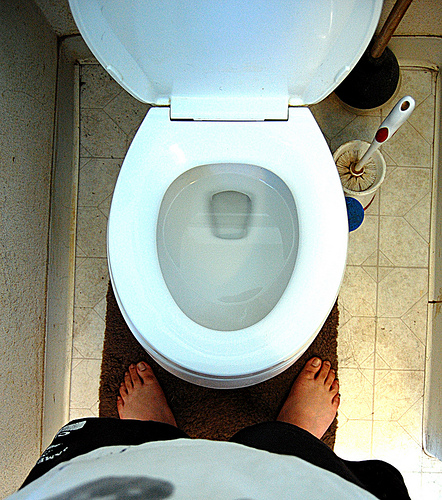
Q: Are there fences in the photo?
A: No, there are no fences.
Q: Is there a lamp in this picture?
A: No, there are no lamps.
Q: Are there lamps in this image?
A: No, there are no lamps.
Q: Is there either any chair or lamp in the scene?
A: No, there are no lamps or chairs.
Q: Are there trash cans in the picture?
A: No, there are no trash cans.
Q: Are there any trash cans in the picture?
A: No, there are no trash cans.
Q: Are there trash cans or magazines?
A: No, there are no trash cans or magazines.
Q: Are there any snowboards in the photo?
A: No, there are no snowboards.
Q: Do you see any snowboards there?
A: No, there are no snowboards.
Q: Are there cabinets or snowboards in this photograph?
A: No, there are no snowboards or cabinets.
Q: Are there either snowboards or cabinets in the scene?
A: No, there are no snowboards or cabinets.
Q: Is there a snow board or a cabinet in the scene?
A: No, there are no snowboards or cabinets.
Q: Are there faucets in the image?
A: No, there are no faucets.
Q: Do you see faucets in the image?
A: No, there are no faucets.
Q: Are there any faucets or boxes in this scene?
A: No, there are no faucets or boxes.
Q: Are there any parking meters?
A: No, there are no parking meters.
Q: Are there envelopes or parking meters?
A: No, there are no parking meters or envelopes.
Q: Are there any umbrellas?
A: No, there are no umbrellas.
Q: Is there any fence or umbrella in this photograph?
A: No, there are no umbrellas or fences.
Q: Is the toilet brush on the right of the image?
A: Yes, the toilet brush is on the right of the image.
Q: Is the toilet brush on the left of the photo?
A: No, the toilet brush is on the right of the image.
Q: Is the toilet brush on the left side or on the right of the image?
A: The toilet brush is on the right of the image.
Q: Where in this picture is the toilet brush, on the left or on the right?
A: The toilet brush is on the right of the image.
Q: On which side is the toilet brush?
A: The toilet brush is on the right of the image.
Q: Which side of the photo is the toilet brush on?
A: The toilet brush is on the right of the image.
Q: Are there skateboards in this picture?
A: No, there are no skateboards.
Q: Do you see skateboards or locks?
A: No, there are no skateboards or locks.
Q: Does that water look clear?
A: Yes, the water is clear.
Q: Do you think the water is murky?
A: No, the water is clear.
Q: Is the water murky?
A: No, the water is clear.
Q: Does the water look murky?
A: No, the water is clear.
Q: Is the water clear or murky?
A: The water is clear.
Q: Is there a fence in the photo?
A: No, there are no fences.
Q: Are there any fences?
A: No, there are no fences.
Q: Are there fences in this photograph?
A: No, there are no fences.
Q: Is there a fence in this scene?
A: No, there are no fences.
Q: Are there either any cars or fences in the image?
A: No, there are no fences or cars.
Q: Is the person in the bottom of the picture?
A: Yes, the person is in the bottom of the image.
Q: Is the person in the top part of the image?
A: No, the person is in the bottom of the image.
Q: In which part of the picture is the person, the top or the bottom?
A: The person is in the bottom of the image.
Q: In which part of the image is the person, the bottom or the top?
A: The person is in the bottom of the image.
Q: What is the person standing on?
A: The person is standing on the rug.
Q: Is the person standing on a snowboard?
A: No, the person is standing on the rug.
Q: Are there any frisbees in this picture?
A: No, there are no frisbees.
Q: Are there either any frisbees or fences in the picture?
A: No, there are no frisbees or fences.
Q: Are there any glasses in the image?
A: No, there are no glasses.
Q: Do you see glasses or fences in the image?
A: No, there are no glasses or fences.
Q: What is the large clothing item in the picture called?
A: The clothing item is a shirt.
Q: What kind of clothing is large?
A: The clothing is a shirt.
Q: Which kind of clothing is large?
A: The clothing is a shirt.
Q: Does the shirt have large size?
A: Yes, the shirt is large.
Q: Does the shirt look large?
A: Yes, the shirt is large.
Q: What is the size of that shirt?
A: The shirt is large.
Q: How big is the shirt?
A: The shirt is large.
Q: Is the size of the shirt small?
A: No, the shirt is large.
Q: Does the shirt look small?
A: No, the shirt is large.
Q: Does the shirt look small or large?
A: The shirt is large.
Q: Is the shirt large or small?
A: The shirt is large.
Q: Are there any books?
A: No, there are no books.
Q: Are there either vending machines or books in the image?
A: No, there are no books or vending machines.